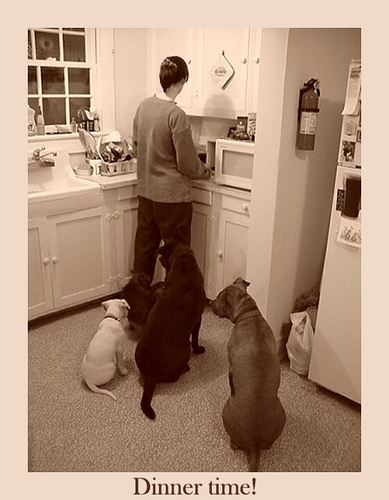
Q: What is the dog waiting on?
A: Food.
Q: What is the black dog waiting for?
A: Food.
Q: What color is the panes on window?
A: White.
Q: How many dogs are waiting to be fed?
A: Three.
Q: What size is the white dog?
A: Small.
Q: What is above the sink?
A: Window.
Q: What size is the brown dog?
A: Large.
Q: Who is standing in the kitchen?
A: A woman.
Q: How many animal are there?
A: Four.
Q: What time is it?
A: Dinner time.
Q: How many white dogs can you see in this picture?
A: 1.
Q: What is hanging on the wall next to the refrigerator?
A: Fire extinguisher.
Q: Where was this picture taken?
A: In a kitchen.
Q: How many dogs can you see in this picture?
A: 3.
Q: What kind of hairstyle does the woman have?
A: Ponytail.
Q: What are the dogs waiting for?
A: Dinner.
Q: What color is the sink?
A: White.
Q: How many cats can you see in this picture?
A: 1.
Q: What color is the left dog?
A: White.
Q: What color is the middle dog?
A: Black.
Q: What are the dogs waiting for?
A: Food.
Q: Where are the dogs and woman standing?
A: Kitchen.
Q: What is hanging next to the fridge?
A: Fire extinguisher.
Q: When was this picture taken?
A: Night time.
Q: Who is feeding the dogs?
A: A woman.